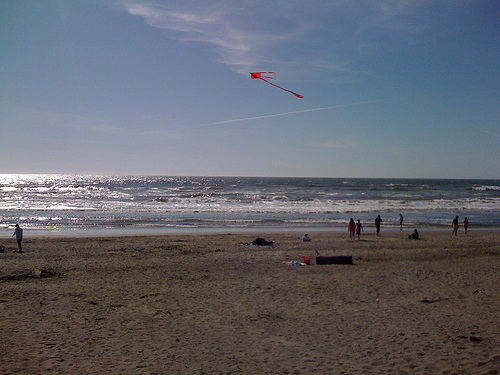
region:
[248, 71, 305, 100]
kite is red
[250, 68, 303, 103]
kite has long tail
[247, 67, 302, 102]
red kite is in sky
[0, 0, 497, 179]
sky is blue and clear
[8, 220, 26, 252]
person is standing on beach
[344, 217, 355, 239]
person is standing on beach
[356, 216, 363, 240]
person is standing on beach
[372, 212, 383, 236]
person is standing on beach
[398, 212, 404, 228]
person is standing on beach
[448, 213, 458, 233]
person is standing on beach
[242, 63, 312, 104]
red kite in the air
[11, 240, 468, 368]
a beach area with lots of sand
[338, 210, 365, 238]
people are on the beach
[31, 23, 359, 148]
the clear blue sky above the ocean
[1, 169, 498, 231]
the ocean in the background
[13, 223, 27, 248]
a person wearing white on the beach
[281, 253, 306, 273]
someone is laying down on the beach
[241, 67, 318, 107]
a kite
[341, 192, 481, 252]
people enjoying the beach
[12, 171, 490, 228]
ocean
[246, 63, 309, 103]
the kite is red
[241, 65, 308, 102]
the kite is flying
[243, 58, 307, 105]
the kite is in the air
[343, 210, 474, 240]
the people are standing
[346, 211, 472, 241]
the people are near the ocean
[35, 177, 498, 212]
the ocean is blue and white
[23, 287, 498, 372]
the sand is brown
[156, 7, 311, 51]
the sky has clouds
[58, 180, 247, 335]
the ocean is beside the sand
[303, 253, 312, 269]
the bucket is red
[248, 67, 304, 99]
An orange kite in the sky.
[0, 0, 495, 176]
The sky is mostly blue and sunny.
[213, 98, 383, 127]
A jet trail is in the sky.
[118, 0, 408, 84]
Thin clouds are high in the sky.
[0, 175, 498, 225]
Breaking waves on the water.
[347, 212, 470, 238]
Seven people are on the beach.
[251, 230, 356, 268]
A red sand pail with a person sitting in a beach area and a log and lumpy object.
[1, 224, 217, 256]
Foot prints in the sand behind and in front of a person.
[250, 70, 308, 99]
A kite has three tails.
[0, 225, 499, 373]
Sand is covered by many footprints.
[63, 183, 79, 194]
ripple in the ocean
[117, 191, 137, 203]
ripple in the ocean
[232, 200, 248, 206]
ripple in the ocean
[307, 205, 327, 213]
ripple in the ocean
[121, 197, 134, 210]
ripple in the ocean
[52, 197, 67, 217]
ripple in the ocean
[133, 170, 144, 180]
ripple in the ocean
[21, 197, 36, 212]
ripple in the ocean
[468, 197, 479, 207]
ripple in the ocean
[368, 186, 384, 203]
ripple in the ocean